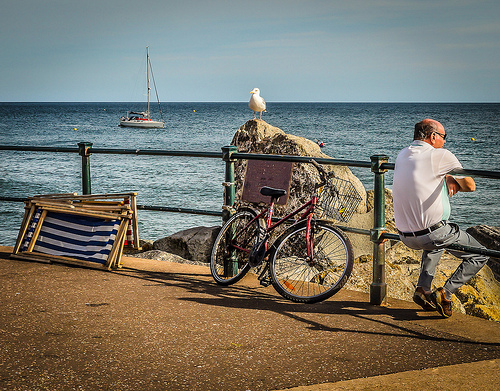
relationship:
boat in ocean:
[121, 43, 169, 131] [1, 103, 498, 249]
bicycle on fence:
[186, 158, 355, 304] [2, 140, 494, 312]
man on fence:
[388, 114, 492, 322] [4, 133, 497, 329]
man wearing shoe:
[388, 114, 492, 322] [409, 283, 437, 313]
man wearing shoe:
[388, 114, 492, 322] [427, 284, 454, 319]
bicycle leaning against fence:
[186, 158, 355, 304] [2, 140, 494, 312]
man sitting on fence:
[388, 114, 492, 322] [4, 133, 497, 329]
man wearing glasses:
[388, 114, 492, 322] [431, 127, 448, 140]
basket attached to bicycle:
[319, 173, 363, 224] [186, 158, 355, 304]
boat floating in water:
[121, 43, 169, 131] [0, 100, 499, 245]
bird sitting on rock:
[248, 88, 268, 123] [114, 115, 499, 325]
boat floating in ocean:
[121, 43, 171, 131] [1, 103, 495, 280]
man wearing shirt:
[391, 114, 489, 319] [391, 139, 461, 233]